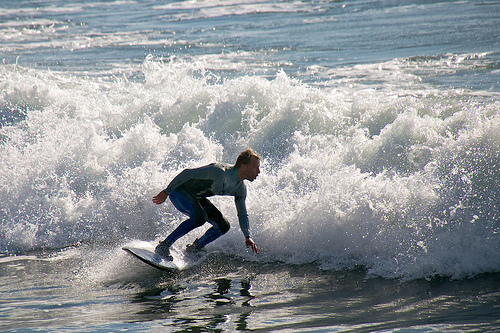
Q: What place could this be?
A: It is an ocean.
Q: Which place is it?
A: It is an ocean.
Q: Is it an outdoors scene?
A: Yes, it is outdoors.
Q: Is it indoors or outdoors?
A: It is outdoors.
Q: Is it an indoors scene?
A: No, it is outdoors.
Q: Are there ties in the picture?
A: No, there are no ties.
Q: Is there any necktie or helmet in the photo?
A: No, there are no ties or helmets.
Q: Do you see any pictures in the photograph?
A: No, there are no pictures.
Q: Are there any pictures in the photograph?
A: No, there are no pictures.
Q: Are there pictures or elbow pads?
A: No, there are no pictures or elbow pads.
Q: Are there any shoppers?
A: No, there are no shoppers.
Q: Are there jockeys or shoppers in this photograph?
A: No, there are no shoppers or jockeys.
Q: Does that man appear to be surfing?
A: Yes, the man is surfing.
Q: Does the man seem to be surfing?
A: Yes, the man is surfing.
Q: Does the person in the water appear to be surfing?
A: Yes, the man is surfing.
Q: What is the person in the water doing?
A: The man is surfing.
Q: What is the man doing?
A: The man is surfing.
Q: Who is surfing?
A: The man is surfing.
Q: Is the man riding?
A: No, the man is surfing.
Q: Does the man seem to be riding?
A: No, the man is surfing.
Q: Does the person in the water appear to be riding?
A: No, the man is surfing.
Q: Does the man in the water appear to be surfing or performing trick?
A: The man is surfing.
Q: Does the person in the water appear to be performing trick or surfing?
A: The man is surfing.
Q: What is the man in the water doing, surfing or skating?
A: The man is surfing.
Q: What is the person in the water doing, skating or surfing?
A: The man is surfing.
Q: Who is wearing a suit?
A: The man is wearing a suit.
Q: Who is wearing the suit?
A: The man is wearing a suit.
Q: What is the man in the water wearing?
A: The man is wearing a suit.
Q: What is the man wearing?
A: The man is wearing a suit.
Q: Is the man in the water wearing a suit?
A: Yes, the man is wearing a suit.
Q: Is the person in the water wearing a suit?
A: Yes, the man is wearing a suit.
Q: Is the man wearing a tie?
A: No, the man is wearing a suit.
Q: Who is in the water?
A: The man is in the water.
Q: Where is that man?
A: The man is in the water.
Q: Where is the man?
A: The man is in the water.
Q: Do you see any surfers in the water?
A: No, there is a man in the water.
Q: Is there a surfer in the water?
A: No, there is a man in the water.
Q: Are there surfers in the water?
A: No, there is a man in the water.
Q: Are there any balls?
A: No, there are no balls.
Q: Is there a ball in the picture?
A: No, there are no balls.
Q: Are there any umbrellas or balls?
A: No, there are no balls or umbrellas.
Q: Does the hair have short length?
A: Yes, the hair is short.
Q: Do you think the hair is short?
A: Yes, the hair is short.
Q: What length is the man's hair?
A: The hair is short.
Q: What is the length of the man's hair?
A: The hair is short.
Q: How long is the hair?
A: The hair is short.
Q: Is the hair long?
A: No, the hair is short.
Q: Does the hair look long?
A: No, the hair is short.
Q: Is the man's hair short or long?
A: The hair is short.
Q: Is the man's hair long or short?
A: The hair is short.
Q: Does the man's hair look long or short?
A: The hair is short.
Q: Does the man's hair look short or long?
A: The hair is short.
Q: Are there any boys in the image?
A: No, there are no boys.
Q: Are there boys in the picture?
A: No, there are no boys.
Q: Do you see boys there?
A: No, there are no boys.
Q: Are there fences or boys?
A: No, there are no boys or fences.